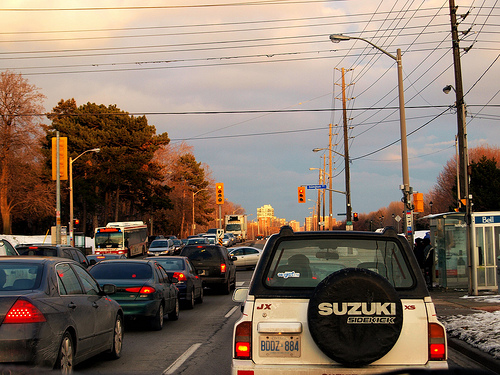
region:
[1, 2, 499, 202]
the blue sky with many white clouds in it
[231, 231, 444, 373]
the SVU sitting on the road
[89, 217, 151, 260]
the bus parked on the side of the road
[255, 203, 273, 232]
the tall building down the road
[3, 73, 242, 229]
many trees on the side of the road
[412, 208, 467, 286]
a bus stop on the side of the road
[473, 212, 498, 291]
the pay phone next to the bus stop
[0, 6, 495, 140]
the power lines attached to the pole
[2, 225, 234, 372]
the cars sitting in the road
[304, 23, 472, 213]
the poles sitting by the road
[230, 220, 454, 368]
rear view of white Suzuki truck in traffic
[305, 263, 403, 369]
black covered spare tire with white letters reading "Suzuki" on back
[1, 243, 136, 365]
blue sedan stopped with brake light lit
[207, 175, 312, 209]
two yellow traiic lights indicating stop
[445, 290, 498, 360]
snow melting on sidewalk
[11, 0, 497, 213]
ominous sky indicating storm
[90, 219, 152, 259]
large white bus with orange digitel display across top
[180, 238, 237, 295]
black SUV truck stipped at light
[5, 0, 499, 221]
ekectrical power lines above street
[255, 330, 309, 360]
white license with blue numbers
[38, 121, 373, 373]
view is in the street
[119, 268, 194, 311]
the car lights are on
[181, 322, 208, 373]
the road is made of ashphalt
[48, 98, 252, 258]
trees are next to the road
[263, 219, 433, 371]
the car is a model of suzuki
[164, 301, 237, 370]
the road has a white lane in the middle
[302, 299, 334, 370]
Black tire on the back of white truck.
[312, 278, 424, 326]
Black tire on the back of white truck.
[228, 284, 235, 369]
Black tire on the back of white truck.